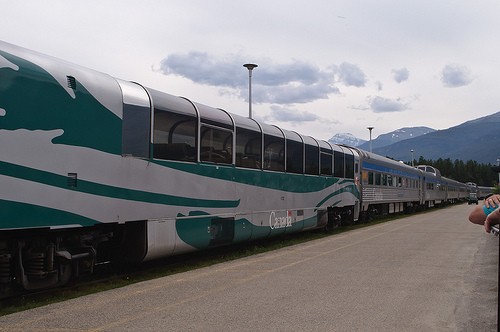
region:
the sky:
[170, 42, 318, 106]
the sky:
[223, 51, 314, 118]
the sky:
[251, 54, 368, 169]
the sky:
[238, 5, 375, 255]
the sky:
[254, 50, 326, 104]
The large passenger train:
[0, 31, 490, 301]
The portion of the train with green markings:
[0, 38, 364, 295]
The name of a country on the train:
[267, 207, 297, 234]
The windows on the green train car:
[138, 83, 357, 182]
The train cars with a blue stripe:
[357, 145, 492, 223]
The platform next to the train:
[0, 197, 499, 329]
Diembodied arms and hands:
[456, 190, 496, 238]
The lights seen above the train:
[242, 60, 417, 168]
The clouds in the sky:
[154, 41, 476, 131]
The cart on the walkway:
[462, 187, 484, 211]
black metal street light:
[242, 62, 259, 75]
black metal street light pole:
[245, 65, 257, 115]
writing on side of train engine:
[261, 210, 298, 230]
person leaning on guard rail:
[460, 185, 498, 241]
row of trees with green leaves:
[441, 157, 498, 178]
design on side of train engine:
[12, 80, 125, 224]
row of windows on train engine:
[143, 115, 354, 179]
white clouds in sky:
[257, 52, 339, 115]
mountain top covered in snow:
[330, 125, 366, 150]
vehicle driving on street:
[460, 190, 479, 208]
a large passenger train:
[1, 37, 498, 309]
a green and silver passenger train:
[0, 39, 361, 291]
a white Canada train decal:
[264, 207, 296, 232]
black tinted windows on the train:
[139, 81, 354, 181]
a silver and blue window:
[363, 145, 498, 224]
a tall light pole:
[243, 62, 257, 119]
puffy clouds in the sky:
[147, 37, 482, 132]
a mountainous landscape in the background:
[320, 108, 498, 185]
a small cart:
[466, 189, 480, 205]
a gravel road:
[2, 196, 498, 329]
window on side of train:
[145, 110, 200, 161]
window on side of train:
[202, 122, 230, 163]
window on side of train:
[240, 133, 262, 169]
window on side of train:
[262, 140, 282, 173]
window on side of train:
[285, 140, 300, 171]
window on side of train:
[302, 146, 319, 172]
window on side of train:
[318, 156, 335, 179]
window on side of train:
[333, 154, 348, 173]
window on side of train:
[373, 175, 380, 185]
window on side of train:
[384, 176, 392, 188]